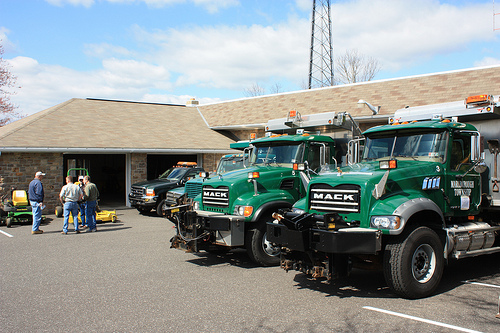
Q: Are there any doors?
A: Yes, there is a door.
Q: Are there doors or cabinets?
A: Yes, there is a door.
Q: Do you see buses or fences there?
A: No, there are no fences or buses.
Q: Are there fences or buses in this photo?
A: No, there are no fences or buses.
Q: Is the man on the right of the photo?
A: No, the man is on the left of the image.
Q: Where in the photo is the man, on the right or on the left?
A: The man is on the left of the image.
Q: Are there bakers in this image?
A: No, there are no bakers.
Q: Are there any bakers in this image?
A: No, there are no bakers.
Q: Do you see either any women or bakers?
A: No, there are no bakers or women.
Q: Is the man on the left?
A: Yes, the man is on the left of the image.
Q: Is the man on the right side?
A: No, the man is on the left of the image.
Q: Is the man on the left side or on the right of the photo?
A: The man is on the left of the image.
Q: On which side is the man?
A: The man is on the left of the image.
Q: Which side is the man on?
A: The man is on the left of the image.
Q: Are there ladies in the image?
A: No, there are no ladies.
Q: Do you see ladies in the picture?
A: No, there are no ladies.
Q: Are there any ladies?
A: No, there are no ladies.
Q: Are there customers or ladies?
A: No, there are no ladies or customers.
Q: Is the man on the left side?
A: Yes, the man is on the left of the image.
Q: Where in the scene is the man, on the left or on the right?
A: The man is on the left of the image.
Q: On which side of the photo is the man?
A: The man is on the left of the image.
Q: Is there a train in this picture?
A: No, there are no trains.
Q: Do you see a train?
A: No, there are no trains.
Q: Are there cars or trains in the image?
A: No, there are no trains or cars.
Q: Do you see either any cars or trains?
A: No, there are no trains or cars.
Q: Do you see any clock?
A: No, there are no clocks.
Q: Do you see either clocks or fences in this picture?
A: No, there are no clocks or fences.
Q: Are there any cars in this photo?
A: No, there are no cars.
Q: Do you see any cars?
A: No, there are no cars.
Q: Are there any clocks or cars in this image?
A: No, there are no cars or clocks.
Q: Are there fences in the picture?
A: No, there are no fences.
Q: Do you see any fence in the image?
A: No, there are no fences.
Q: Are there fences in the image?
A: No, there are no fences.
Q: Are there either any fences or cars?
A: No, there are no fences or cars.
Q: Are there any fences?
A: No, there are no fences.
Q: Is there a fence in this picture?
A: No, there are no fences.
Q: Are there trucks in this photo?
A: Yes, there is a truck.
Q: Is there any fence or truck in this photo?
A: Yes, there is a truck.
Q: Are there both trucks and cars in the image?
A: No, there is a truck but no cars.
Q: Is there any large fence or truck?
A: Yes, there is a large truck.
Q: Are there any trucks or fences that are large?
A: Yes, the truck is large.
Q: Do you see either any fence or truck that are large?
A: Yes, the truck is large.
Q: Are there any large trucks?
A: Yes, there is a large truck.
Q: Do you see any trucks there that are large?
A: Yes, there is a truck that is large.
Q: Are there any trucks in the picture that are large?
A: Yes, there is a truck that is large.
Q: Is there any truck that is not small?
A: Yes, there is a large truck.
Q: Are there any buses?
A: No, there are no buses.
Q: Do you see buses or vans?
A: No, there are no buses or vans.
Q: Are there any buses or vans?
A: No, there are no buses or vans.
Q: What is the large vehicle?
A: The vehicle is a truck.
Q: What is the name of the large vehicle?
A: The vehicle is a truck.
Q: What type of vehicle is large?
A: The vehicle is a truck.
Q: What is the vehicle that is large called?
A: The vehicle is a truck.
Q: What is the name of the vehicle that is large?
A: The vehicle is a truck.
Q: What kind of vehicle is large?
A: The vehicle is a truck.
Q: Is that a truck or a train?
A: That is a truck.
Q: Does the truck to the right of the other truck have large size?
A: Yes, the truck is large.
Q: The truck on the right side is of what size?
A: The truck is large.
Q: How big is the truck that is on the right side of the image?
A: The truck is large.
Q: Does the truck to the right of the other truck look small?
A: No, the truck is large.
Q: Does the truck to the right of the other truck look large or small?
A: The truck is large.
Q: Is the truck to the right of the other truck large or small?
A: The truck is large.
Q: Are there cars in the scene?
A: No, there are no cars.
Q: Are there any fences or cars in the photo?
A: No, there are no cars or fences.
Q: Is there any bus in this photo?
A: No, there are no buses.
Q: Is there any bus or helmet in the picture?
A: No, there are no buses or helmets.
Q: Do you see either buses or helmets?
A: No, there are no buses or helmets.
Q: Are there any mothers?
A: No, there are no mothers.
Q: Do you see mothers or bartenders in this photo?
A: No, there are no mothers or bartenders.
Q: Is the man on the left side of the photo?
A: Yes, the man is on the left of the image.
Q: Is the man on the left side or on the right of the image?
A: The man is on the left of the image.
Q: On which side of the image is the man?
A: The man is on the left of the image.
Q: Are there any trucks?
A: Yes, there is a truck.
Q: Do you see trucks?
A: Yes, there is a truck.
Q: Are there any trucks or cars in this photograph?
A: Yes, there is a truck.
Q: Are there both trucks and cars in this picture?
A: No, there is a truck but no cars.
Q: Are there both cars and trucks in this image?
A: No, there is a truck but no cars.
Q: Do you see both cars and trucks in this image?
A: No, there is a truck but no cars.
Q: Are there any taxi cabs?
A: No, there are no taxi cabs.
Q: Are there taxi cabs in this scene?
A: No, there are no taxi cabs.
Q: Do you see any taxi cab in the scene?
A: No, there are no taxis.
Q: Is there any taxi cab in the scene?
A: No, there are no taxis.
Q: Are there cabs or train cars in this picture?
A: No, there are no cabs or train cars.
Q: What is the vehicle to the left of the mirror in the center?
A: The vehicle is a truck.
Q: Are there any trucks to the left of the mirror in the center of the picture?
A: Yes, there is a truck to the left of the mirror.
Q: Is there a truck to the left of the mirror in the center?
A: Yes, there is a truck to the left of the mirror.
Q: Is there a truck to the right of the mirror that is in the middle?
A: No, the truck is to the left of the mirror.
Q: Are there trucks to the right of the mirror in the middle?
A: No, the truck is to the left of the mirror.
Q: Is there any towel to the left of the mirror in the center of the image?
A: No, there is a truck to the left of the mirror.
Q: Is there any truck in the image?
A: Yes, there is a truck.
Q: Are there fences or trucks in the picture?
A: Yes, there is a truck.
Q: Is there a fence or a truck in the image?
A: Yes, there is a truck.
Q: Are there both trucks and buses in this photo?
A: No, there is a truck but no buses.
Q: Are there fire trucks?
A: No, there are no fire trucks.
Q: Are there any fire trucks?
A: No, there are no fire trucks.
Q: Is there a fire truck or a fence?
A: No, there are no fire trucks or fences.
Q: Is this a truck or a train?
A: This is a truck.